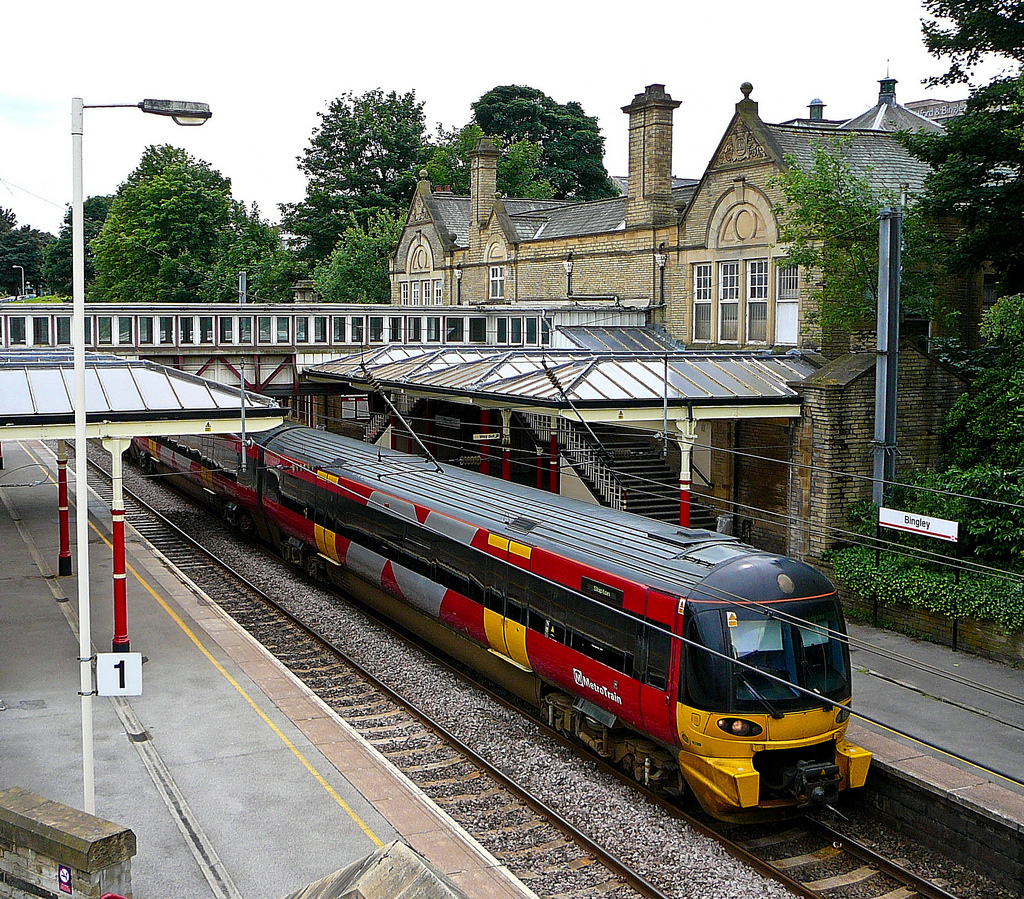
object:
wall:
[570, 232, 658, 300]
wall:
[460, 266, 488, 299]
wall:
[506, 239, 564, 297]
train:
[55, 339, 874, 830]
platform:
[38, 664, 400, 858]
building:
[389, 59, 1024, 668]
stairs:
[517, 407, 723, 543]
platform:
[838, 617, 1022, 831]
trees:
[87, 142, 267, 315]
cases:
[514, 408, 728, 534]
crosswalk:
[0, 436, 389, 899]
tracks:
[726, 809, 958, 899]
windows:
[691, 260, 714, 301]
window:
[566, 580, 643, 679]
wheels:
[633, 765, 647, 782]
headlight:
[835, 701, 852, 725]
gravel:
[629, 819, 661, 851]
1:
[113, 658, 129, 688]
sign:
[93, 650, 143, 697]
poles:
[102, 438, 132, 652]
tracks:
[43, 427, 661, 897]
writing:
[903, 513, 931, 530]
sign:
[874, 503, 961, 543]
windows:
[728, 615, 849, 702]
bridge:
[0, 290, 647, 356]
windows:
[743, 257, 770, 303]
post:
[69, 95, 99, 816]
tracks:
[121, 376, 874, 835]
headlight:
[715, 714, 762, 738]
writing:
[570, 667, 625, 706]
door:
[640, 586, 676, 746]